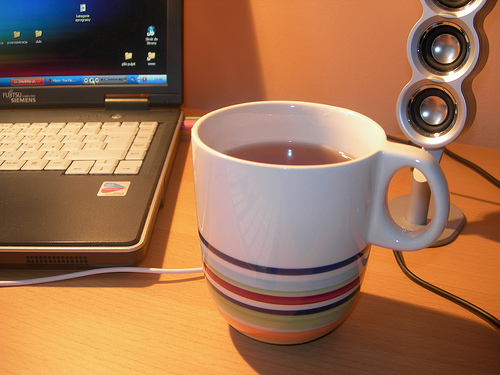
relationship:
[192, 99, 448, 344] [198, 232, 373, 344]
mug with multicolored stripes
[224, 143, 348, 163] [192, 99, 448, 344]
tea in mug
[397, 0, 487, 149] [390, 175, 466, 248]
speaker on a support post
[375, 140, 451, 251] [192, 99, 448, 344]
handle on mug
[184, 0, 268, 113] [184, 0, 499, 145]
shadow of monitor on wall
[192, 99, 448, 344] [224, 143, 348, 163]
mug with liquid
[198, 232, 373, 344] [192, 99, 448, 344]
stripes on mug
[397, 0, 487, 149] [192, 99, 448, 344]
speaker behind mug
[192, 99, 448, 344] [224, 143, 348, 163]
mug with tea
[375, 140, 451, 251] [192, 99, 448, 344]
handle of mug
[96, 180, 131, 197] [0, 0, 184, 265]
logo sticker on laptop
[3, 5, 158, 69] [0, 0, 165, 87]
desktop icons on laptop screen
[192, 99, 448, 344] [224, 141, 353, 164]
mug of coffee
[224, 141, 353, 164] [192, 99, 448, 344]
coffee in a mug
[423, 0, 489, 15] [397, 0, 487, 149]
top part of speaker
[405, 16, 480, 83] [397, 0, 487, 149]
center circle of speaker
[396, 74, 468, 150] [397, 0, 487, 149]
bottom circle of speaker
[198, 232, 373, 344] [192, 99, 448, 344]
stripes on bottom of mug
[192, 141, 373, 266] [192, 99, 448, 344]
upper half of mug